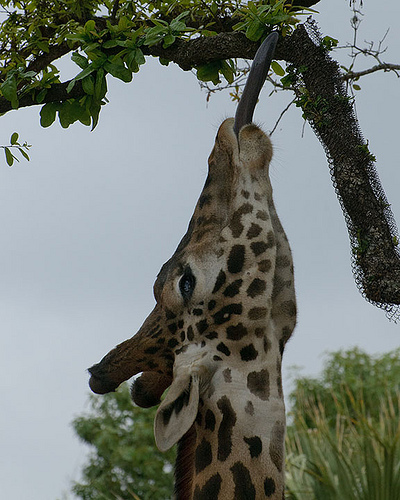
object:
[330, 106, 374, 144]
mesh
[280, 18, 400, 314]
branch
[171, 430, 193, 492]
hair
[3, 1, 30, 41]
leaves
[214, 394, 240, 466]
spot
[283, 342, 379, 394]
trees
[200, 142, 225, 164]
nose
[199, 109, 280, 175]
mouth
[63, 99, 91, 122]
leaves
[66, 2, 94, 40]
leaves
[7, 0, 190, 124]
branch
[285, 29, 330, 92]
mesh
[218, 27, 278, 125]
tongue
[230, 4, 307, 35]
leaf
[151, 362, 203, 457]
ear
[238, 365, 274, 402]
spot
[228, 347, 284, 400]
fur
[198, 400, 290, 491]
fur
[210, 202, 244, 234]
spots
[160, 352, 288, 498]
neck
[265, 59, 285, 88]
vegetable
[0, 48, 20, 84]
leaves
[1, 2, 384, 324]
large tree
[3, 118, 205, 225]
sky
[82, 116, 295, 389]
head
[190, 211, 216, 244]
spots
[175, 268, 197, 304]
eye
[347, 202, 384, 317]
tree branch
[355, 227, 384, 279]
netting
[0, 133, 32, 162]
leaves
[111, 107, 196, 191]
patch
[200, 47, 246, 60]
bark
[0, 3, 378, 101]
tree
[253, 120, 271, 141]
hair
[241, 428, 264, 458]
spots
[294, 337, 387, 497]
plants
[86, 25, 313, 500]
giraffe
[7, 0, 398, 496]
safari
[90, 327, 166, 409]
giraffe's horn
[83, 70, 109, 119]
leaves